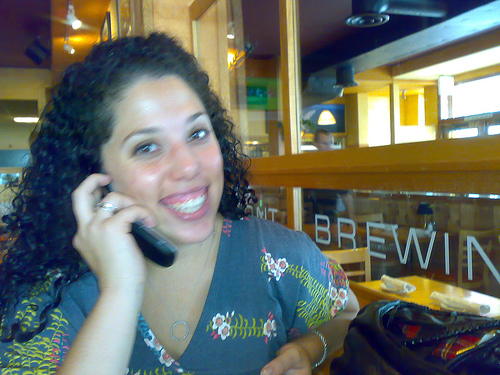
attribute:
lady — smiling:
[6, 15, 352, 331]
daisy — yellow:
[261, 339, 278, 347]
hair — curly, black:
[76, 61, 130, 82]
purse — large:
[409, 325, 487, 363]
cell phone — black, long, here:
[135, 233, 180, 263]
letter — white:
[397, 222, 415, 255]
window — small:
[440, 64, 489, 113]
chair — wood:
[334, 240, 398, 284]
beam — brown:
[372, 23, 452, 72]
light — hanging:
[57, 6, 104, 36]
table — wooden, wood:
[350, 291, 426, 351]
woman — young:
[75, 119, 315, 338]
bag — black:
[423, 294, 483, 360]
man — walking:
[304, 136, 361, 162]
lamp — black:
[402, 187, 462, 247]